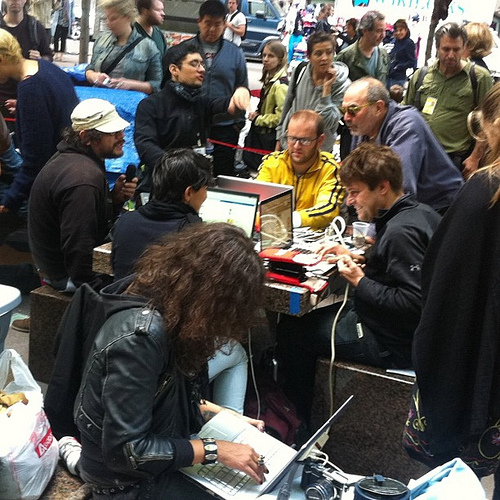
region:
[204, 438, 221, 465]
BAND AROUND THE WRIST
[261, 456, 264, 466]
RING ON THE FINGURE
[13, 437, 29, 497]
WHITE BAG ON THE TABLE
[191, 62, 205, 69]
BOY WEARING EYE GLASSES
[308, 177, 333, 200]
MAN WEARING A YELLOW JACKET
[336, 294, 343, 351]
WHITE CORD HANGING DOWN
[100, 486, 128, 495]
BELT IN THE PANTS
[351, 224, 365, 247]
CUP ON THE TABLE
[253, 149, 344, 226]
a yellow and black jacket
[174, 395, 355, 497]
an open laptop computer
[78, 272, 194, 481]
a black leather jacket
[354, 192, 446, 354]
a black jacket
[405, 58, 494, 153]
a man's lime green shirt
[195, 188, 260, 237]
a laptop computer monitor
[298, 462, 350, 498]
a digital camera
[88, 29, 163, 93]
a blue jean jacket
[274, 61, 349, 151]
a woman's grey sweatshirt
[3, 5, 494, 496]
people at an electronics convention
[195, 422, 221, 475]
a bracelet with silver medallions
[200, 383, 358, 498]
a laptop on a man's legs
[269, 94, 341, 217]
a balding man wearing glasses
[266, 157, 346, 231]
a yellow jacket with black stripes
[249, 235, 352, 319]
notebooks stacked on a table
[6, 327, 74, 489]
a plastic bag holding items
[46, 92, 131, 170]
a man with a white hat on his head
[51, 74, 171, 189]
a blue tarp covering part of the table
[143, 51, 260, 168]
a man explaining things to others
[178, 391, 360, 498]
a large laptop computer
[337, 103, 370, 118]
dark sunglasses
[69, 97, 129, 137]
a man's hat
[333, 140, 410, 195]
a man's short cut brown hair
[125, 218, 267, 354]
a man's long brown hair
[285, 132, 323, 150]
a man's eyeglasses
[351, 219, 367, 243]
part of a plastic cup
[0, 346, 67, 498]
part of a plastic bag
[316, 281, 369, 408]
a long white cord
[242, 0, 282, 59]
part of a blue van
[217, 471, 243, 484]
keys on the laptop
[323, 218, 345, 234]
a white cord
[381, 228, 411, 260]
a black jacket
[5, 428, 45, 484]
a plastic bag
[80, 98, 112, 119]
man wearing a hat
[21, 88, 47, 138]
a blue sweater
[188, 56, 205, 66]
man wearing eye glasses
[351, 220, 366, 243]
a cup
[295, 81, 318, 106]
a grey hoodie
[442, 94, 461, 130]
a green shirt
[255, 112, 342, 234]
person waiting in line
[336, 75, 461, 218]
person waiting in line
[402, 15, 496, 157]
person waiting in line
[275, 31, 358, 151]
person waiting in line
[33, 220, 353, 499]
lady typing on laptop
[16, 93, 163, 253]
man holding microphone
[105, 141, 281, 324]
man sitting in front of lap top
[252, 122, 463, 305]
man typing on lap top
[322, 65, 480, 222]
man looking at lap top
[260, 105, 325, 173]
man wearing glasses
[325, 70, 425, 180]
man wearing glasses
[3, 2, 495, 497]
Daytime view, locality uncertain, cooler season evident.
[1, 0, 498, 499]
View of large amount of disorganized people, standing and sitting.